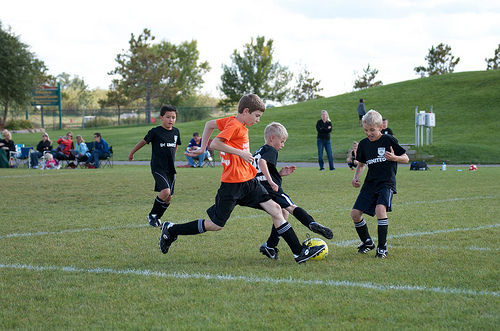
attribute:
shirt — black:
[140, 122, 181, 160]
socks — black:
[351, 217, 389, 247]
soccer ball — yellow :
[305, 238, 329, 262]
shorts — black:
[350, 180, 397, 216]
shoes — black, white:
[181, 204, 328, 278]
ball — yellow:
[294, 232, 345, 272]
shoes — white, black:
[165, 210, 377, 314]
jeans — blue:
[311, 145, 336, 170]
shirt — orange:
[215, 116, 257, 183]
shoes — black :
[142, 199, 192, 258]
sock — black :
[167, 202, 207, 242]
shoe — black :
[140, 204, 185, 268]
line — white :
[45, 240, 484, 316]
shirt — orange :
[200, 106, 260, 187]